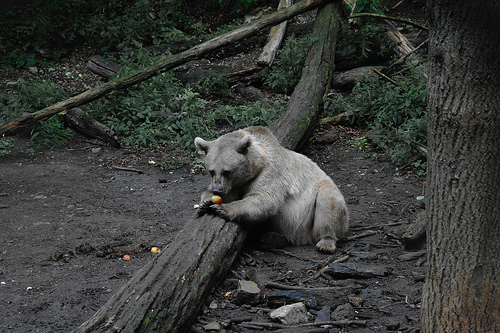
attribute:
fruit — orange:
[209, 192, 223, 206]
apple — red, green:
[211, 191, 221, 203]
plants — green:
[119, 84, 273, 128]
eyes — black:
[210, 167, 233, 178]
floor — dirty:
[10, 177, 136, 265]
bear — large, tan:
[186, 128, 356, 260]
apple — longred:
[119, 249, 131, 260]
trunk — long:
[137, 212, 237, 275]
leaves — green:
[335, 65, 425, 149]